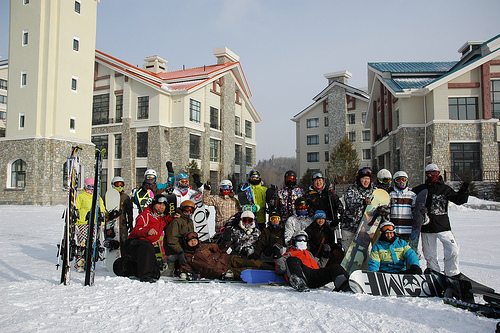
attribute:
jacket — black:
[414, 182, 465, 230]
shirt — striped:
[365, 180, 426, 244]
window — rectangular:
[210, 134, 221, 161]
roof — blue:
[363, 32, 498, 92]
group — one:
[72, 164, 472, 294]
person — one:
[413, 162, 473, 276]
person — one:
[388, 169, 431, 244]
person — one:
[365, 221, 423, 274]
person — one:
[128, 193, 182, 283]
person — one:
[304, 173, 344, 225]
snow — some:
[3, 193, 498, 331]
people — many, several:
[416, 162, 473, 267]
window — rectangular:
[303, 149, 320, 165]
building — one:
[0, 36, 265, 206]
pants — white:
[415, 231, 463, 287]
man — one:
[182, 231, 230, 263]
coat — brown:
[194, 247, 221, 274]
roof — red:
[129, 75, 201, 95]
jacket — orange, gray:
[365, 237, 425, 274]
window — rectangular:
[299, 114, 321, 128]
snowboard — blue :
[238, 266, 280, 292]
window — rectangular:
[445, 97, 487, 123]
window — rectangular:
[304, 114, 323, 129]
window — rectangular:
[184, 95, 203, 124]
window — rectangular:
[307, 134, 323, 152]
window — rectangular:
[5, 157, 32, 192]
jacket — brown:
[185, 247, 227, 277]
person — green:
[362, 216, 426, 278]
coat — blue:
[365, 234, 422, 272]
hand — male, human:
[146, 230, 158, 236]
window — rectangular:
[242, 146, 254, 166]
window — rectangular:
[245, 119, 253, 142]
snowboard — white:
[347, 267, 464, 299]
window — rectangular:
[237, 102, 269, 136]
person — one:
[24, 171, 166, 266]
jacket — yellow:
[65, 170, 139, 240]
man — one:
[385, 166, 420, 239]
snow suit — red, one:
[125, 215, 167, 237]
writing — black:
[363, 270, 439, 294]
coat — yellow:
[69, 189, 107, 227]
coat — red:
[130, 207, 168, 245]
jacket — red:
[134, 210, 170, 237]